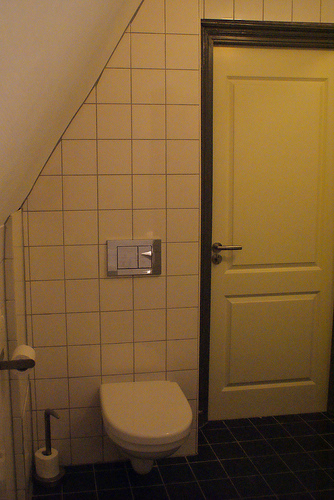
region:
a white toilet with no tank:
[95, 376, 194, 491]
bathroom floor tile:
[223, 437, 293, 499]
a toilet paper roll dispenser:
[1, 338, 40, 408]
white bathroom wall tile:
[64, 299, 187, 379]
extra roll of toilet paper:
[32, 406, 71, 493]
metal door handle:
[212, 229, 254, 268]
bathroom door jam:
[195, 94, 232, 294]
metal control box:
[96, 234, 175, 283]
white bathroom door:
[207, 39, 331, 248]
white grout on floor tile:
[243, 443, 325, 492]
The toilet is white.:
[86, 373, 191, 470]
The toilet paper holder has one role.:
[42, 396, 66, 489]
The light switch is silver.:
[101, 226, 169, 288]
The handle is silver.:
[204, 236, 243, 277]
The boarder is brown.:
[190, 37, 225, 433]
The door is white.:
[207, 41, 332, 409]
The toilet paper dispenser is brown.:
[4, 339, 48, 422]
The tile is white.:
[40, 279, 181, 354]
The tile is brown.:
[223, 445, 329, 496]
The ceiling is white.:
[23, 55, 67, 138]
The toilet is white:
[82, 378, 232, 465]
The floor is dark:
[200, 433, 275, 484]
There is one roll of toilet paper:
[29, 409, 82, 475]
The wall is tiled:
[65, 327, 107, 408]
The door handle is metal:
[207, 234, 258, 265]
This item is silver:
[95, 217, 172, 288]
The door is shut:
[196, 195, 233, 486]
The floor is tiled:
[230, 419, 279, 495]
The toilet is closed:
[94, 375, 214, 475]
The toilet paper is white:
[5, 336, 54, 400]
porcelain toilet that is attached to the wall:
[92, 376, 196, 482]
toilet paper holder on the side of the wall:
[5, 342, 39, 375]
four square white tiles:
[100, 312, 167, 374]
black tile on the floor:
[39, 414, 331, 498]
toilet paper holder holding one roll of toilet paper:
[28, 407, 72, 485]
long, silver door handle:
[214, 237, 242, 254]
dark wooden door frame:
[195, 18, 220, 422]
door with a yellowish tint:
[208, 42, 333, 426]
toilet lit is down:
[90, 376, 204, 456]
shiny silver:
[102, 237, 164, 282]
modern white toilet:
[93, 373, 201, 486]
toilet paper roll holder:
[35, 405, 73, 490]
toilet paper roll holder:
[5, 338, 45, 383]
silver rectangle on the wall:
[103, 231, 169, 283]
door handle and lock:
[207, 236, 245, 272]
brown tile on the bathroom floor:
[217, 444, 273, 492]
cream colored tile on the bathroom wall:
[53, 287, 144, 344]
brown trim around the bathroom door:
[188, 13, 222, 389]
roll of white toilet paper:
[8, 343, 42, 425]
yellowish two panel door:
[215, 47, 329, 416]